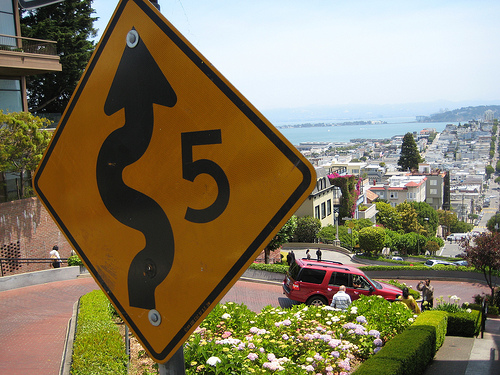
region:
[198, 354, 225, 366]
white flower in field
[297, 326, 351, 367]
beautiful blooming pink flowers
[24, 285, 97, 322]
portion of curvy pink road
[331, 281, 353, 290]
man's blond bald head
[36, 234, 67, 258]
woman in white shirt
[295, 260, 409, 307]
red SUV on the pink road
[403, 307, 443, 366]
carefully manicured green sections of grass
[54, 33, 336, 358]
yellow lines with black words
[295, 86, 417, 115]
mountain range on the horizon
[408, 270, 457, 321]
man taking picture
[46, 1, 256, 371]
yellow sign with black lettering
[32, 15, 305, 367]
sign post indicating curvy road ahead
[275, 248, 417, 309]
red SUV on curvy road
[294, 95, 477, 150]
blue ocean in the background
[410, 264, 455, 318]
man taking a photograph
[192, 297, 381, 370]
little garden patch on side of road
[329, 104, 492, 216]
city downhill from curvy road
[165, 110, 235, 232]
number 5 on yellow sign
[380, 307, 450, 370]
green and well manicured hedges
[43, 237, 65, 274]
woman walking on sidewalk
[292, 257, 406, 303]
A red truck going down the hill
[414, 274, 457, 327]
A person taking a picture.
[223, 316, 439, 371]
Bed of flowers sitting in middle of curve.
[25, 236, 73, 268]
A person walking down ramp.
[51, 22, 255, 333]
A yellow sign with a curvy street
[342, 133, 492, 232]
Tons of building down the mountain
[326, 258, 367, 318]
A man standing on the side of red car.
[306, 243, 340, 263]
People looking at the view.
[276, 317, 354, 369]
The flowers are pink and white.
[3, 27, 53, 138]
A building on the side of the curvy road.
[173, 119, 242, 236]
a black number five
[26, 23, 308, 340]
a yellow road sign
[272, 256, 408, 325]
a red SUV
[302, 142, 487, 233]
a row of homes and businesses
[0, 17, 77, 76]
a buildings balcony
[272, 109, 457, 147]
a body of water in the background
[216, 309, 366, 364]
pink flowers in a garden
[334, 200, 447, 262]
a group of green trees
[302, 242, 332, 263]
people on a sidewalk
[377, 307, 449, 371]
a small green hedge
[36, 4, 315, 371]
a yellow sign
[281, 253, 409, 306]
a red vehicle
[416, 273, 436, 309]
a person standing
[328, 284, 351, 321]
a person standing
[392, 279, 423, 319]
a person standing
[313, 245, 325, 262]
a person standing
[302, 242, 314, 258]
a person standing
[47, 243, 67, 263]
a person standing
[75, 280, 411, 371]
lovely flowers in a home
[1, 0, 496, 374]
a lovely picture